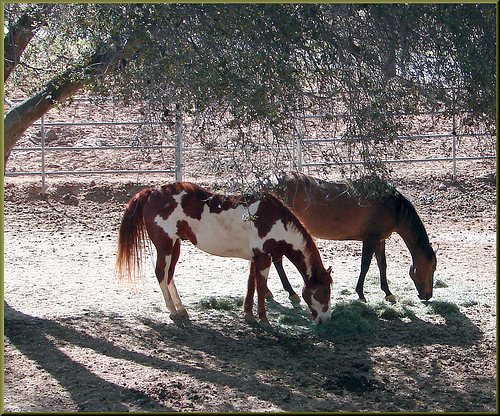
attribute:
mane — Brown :
[267, 195, 325, 277]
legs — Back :
[151, 240, 201, 320]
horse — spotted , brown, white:
[113, 177, 337, 327]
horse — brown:
[135, 174, 458, 327]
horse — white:
[115, 175, 366, 312]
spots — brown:
[161, 180, 221, 220]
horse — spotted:
[126, 162, 376, 324]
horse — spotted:
[96, 181, 364, 313]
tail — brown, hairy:
[116, 163, 172, 296]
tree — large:
[2, 9, 498, 334]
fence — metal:
[2, 91, 492, 187]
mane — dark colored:
[370, 187, 437, 256]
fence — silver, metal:
[4, 84, 498, 198]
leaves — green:
[17, 5, 487, 166]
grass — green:
[161, 265, 486, 386]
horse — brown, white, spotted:
[113, 182, 329, 336]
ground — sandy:
[2, 191, 492, 318]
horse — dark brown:
[237, 171, 435, 316]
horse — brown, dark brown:
[253, 169, 438, 319]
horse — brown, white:
[119, 180, 349, 345]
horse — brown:
[252, 173, 437, 309]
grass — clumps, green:
[253, 300, 392, 340]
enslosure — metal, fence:
[60, 110, 193, 168]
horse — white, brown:
[125, 179, 315, 336]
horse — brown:
[252, 159, 472, 333]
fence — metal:
[71, 102, 147, 142]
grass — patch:
[112, 316, 426, 366]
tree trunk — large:
[16, 91, 46, 151]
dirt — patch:
[89, 128, 144, 169]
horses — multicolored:
[98, 174, 445, 345]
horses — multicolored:
[90, 195, 460, 361]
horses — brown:
[210, 176, 424, 313]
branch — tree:
[358, 44, 438, 93]